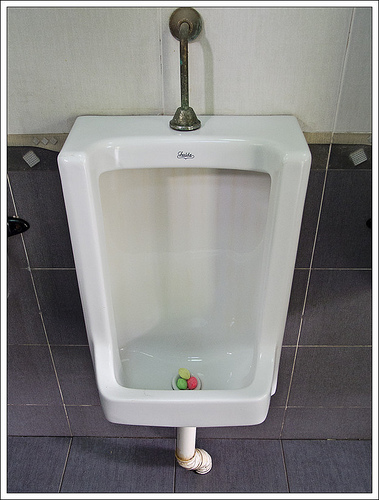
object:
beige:
[302, 131, 370, 143]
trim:
[7, 129, 29, 156]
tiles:
[9, 18, 166, 123]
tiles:
[287, 146, 370, 428]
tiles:
[8, 139, 80, 436]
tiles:
[40, 442, 64, 489]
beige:
[5, 133, 61, 148]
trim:
[347, 132, 370, 144]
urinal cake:
[177, 363, 189, 378]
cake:
[174, 376, 186, 387]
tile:
[335, 438, 371, 491]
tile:
[248, 438, 288, 493]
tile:
[60, 434, 88, 491]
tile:
[7, 435, 29, 490]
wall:
[201, 10, 370, 448]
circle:
[166, 4, 203, 42]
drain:
[170, 422, 213, 475]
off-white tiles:
[281, 4, 371, 113]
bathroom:
[56, 8, 313, 476]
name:
[175, 141, 199, 163]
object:
[7, 214, 30, 239]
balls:
[187, 376, 199, 389]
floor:
[8, 437, 58, 493]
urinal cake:
[187, 377, 195, 386]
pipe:
[172, 425, 218, 476]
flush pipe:
[164, 8, 213, 135]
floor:
[287, 427, 368, 490]